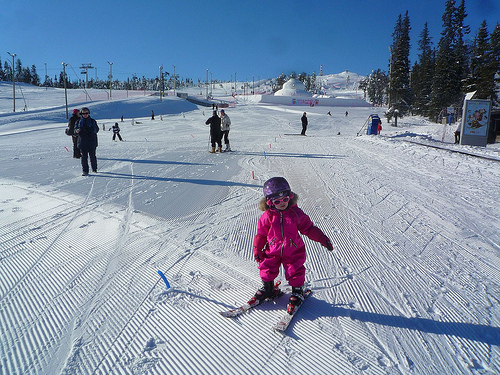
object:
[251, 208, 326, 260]
jacket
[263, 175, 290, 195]
helmet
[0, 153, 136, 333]
tracks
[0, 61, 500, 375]
snow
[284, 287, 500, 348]
shadow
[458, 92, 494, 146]
kiosk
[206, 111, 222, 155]
people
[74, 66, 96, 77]
ski lift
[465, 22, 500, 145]
trees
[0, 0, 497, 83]
sky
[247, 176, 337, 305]
kid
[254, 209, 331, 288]
suit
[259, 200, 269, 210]
fur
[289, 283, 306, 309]
boots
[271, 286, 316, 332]
skis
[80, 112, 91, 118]
glasses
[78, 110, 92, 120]
face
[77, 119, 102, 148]
coat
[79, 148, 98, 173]
pants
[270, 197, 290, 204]
glasses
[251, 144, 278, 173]
ridges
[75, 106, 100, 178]
person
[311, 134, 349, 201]
poles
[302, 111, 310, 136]
person